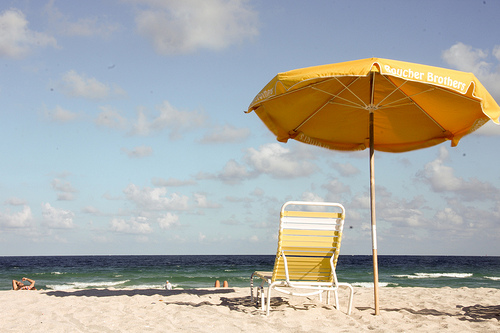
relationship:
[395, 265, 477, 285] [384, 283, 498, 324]
waves breaking on beach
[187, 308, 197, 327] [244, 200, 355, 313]
sand by chair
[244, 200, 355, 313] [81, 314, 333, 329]
chair on beach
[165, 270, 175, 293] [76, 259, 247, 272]
someone close to ocean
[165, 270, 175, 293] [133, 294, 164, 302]
someone on beach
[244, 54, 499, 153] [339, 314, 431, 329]
parasol in sand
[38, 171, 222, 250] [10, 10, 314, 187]
clouds in sky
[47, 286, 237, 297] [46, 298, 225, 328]
shadow on sand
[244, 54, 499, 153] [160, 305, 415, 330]
parasol on beach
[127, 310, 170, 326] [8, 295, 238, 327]
sand on beach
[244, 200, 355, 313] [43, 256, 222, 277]
chair facing water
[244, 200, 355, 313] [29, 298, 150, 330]
chair on sand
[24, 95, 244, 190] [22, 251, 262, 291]
sky above ocean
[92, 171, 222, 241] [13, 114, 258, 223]
clouds in sky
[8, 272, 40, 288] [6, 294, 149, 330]
person on beach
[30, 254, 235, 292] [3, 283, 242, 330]
waves coming to shore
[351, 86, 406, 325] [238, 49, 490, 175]
pole holding umbrella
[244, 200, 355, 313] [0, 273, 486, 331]
chair on beach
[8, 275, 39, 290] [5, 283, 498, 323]
person on beach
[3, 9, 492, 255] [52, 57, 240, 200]
sky with clouds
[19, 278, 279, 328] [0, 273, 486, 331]
sand on beach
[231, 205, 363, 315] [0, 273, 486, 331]
chair on beach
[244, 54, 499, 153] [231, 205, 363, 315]
parasol on chair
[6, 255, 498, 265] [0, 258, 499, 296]
water of ocean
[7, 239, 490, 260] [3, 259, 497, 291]
horizon over ocean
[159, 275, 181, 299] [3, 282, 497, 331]
bird on beach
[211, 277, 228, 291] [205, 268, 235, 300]
knees on someone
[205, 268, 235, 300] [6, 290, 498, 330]
someone on sand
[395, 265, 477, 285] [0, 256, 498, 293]
waves of ocean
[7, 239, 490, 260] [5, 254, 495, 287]
horizon of ocean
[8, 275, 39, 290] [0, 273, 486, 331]
person on beach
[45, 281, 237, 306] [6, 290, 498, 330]
shadows on sand